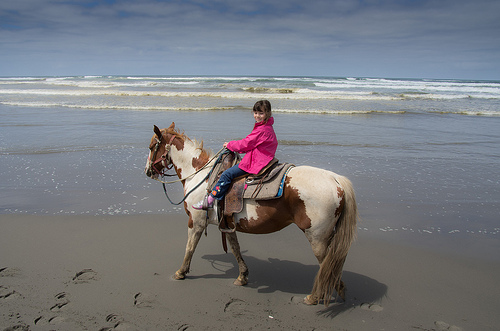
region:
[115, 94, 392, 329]
horse is brown and white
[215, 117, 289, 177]
hot pink jacket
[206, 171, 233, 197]
colors on the jeans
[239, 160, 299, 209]
blanket under the saddle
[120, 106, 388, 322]
horse walking on the saddle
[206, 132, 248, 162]
girl is holding the reins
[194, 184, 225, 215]
foot in the stirrup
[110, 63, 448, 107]
waves in the ocean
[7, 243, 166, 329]
hoof prints in the sand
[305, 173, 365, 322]
horse's tail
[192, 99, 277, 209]
A young girl riding a horse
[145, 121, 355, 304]
A horse walking along a beach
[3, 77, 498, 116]
Waves gently rolling onto the shore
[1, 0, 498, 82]
Light clouds filling up a blue sky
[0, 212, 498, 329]
A wet, sandy beach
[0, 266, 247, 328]
Footprints in the sand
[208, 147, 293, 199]
A saddle on a horse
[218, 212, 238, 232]
A stirrup attached to a saddle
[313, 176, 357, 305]
A horse's tail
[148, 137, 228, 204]
A horses reigns being held by a little girl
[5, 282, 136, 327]
footprints in the sand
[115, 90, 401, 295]
the horse on the beach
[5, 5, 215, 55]
the clouds in the sky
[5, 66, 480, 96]
the waves on the ocean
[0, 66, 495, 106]
the ocean is turbulent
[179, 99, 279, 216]
the girl on the horse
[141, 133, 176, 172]
the bridal of the horse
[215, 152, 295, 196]
the saddle on the hourse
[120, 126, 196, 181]
the head of the horse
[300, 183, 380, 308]
the tail of the horse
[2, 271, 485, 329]
Foot prints in the sand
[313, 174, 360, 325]
Tail on the horse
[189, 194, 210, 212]
Little girls left shoe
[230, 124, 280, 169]
Pink jacket on girl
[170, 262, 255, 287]
Two front horse hoofs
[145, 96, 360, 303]
Little girl riding a horse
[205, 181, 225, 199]
Designs on girls pants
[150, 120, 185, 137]
Two brown horse ears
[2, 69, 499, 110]
Waves off in the distance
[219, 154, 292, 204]
Saddle on the horse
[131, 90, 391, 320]
This is a horse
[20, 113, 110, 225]
Section of a lake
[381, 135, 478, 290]
Section of a lake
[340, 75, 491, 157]
Section of a lake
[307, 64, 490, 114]
Section of a lake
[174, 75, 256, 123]
Section of a lake